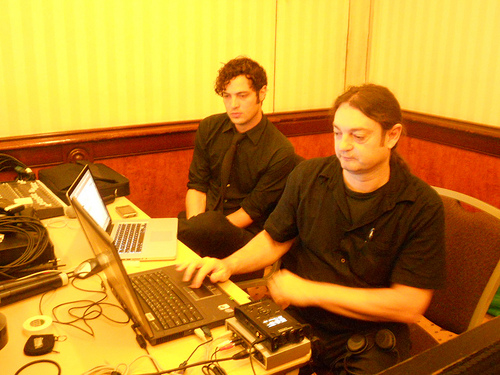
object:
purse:
[23, 333, 53, 355]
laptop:
[65, 193, 248, 344]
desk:
[2, 184, 322, 375]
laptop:
[64, 163, 181, 261]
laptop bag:
[34, 162, 129, 207]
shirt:
[259, 149, 449, 323]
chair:
[428, 186, 500, 357]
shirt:
[181, 113, 299, 220]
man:
[179, 49, 307, 270]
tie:
[217, 130, 242, 214]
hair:
[215, 55, 268, 93]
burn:
[250, 96, 262, 105]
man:
[176, 85, 446, 375]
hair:
[330, 82, 404, 125]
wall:
[0, 0, 500, 146]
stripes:
[0, 0, 21, 135]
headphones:
[343, 328, 405, 373]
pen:
[362, 224, 374, 238]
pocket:
[345, 236, 386, 271]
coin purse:
[21, 333, 57, 355]